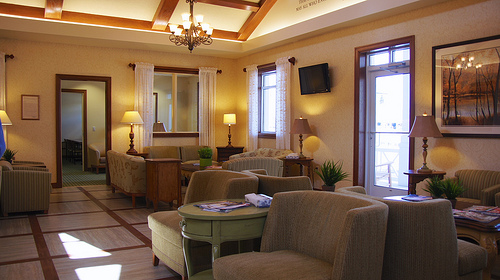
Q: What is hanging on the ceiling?
A: Chandelier.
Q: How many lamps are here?
A: 5.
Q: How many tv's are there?
A: 1.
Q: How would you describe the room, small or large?
A: Large.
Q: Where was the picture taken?
A: In a lobby.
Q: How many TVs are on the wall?
A: 1.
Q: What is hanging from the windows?
A: Curtains.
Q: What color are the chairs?
A: Beige.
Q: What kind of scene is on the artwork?
A: A lake scene.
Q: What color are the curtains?
A: White.